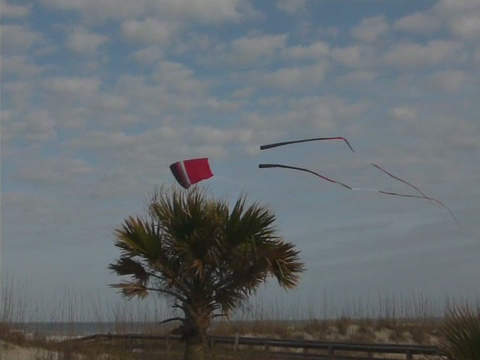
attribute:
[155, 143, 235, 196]
kite — blowing, red, white, black, rectangular, flying, aloft, body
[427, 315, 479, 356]
bush — small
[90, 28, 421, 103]
day — cloudy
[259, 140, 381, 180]
tail — black, long, red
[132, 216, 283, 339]
tree — palm, single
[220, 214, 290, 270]
fonds — green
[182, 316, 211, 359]
trunk — brown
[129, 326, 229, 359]
weeds — short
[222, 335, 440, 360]
rail — metal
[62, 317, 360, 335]
shoreline — ocean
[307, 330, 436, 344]
dune — covered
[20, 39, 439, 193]
sky — cloudy, blue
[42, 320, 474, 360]
grass — growing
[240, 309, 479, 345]
ground — sandy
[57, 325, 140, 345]
post — wooden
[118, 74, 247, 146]
clouds — puffy, white, small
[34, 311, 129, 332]
water — calm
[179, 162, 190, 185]
stripe — red, white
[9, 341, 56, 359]
sand — tan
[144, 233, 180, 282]
leaves — blooming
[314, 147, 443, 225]
streamers — black, red, white